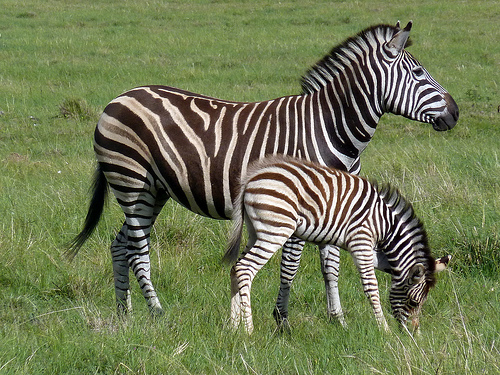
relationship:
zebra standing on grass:
[51, 18, 459, 319] [2, 1, 499, 373]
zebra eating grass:
[210, 152, 437, 343] [2, 1, 499, 373]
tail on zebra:
[209, 184, 248, 274] [210, 152, 437, 343]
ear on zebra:
[390, 21, 413, 52] [51, 18, 459, 319]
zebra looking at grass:
[210, 152, 437, 343] [2, 1, 499, 373]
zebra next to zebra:
[51, 18, 459, 319] [210, 152, 437, 343]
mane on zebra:
[299, 25, 414, 96] [51, 18, 459, 319]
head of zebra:
[370, 20, 458, 132] [51, 18, 459, 319]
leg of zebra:
[233, 226, 297, 338] [210, 152, 437, 343]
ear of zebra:
[399, 260, 425, 291] [210, 152, 437, 343]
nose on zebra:
[442, 93, 461, 120] [51, 18, 459, 319]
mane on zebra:
[360, 174, 439, 291] [210, 152, 437, 343]